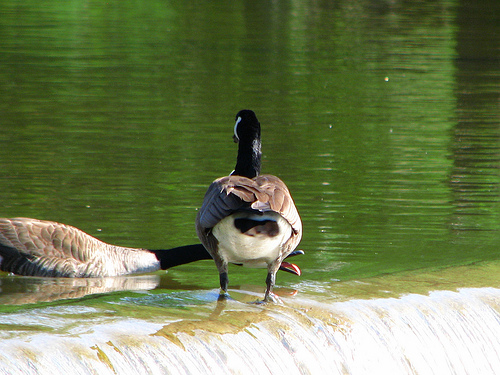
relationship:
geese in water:
[8, 125, 300, 309] [129, 27, 389, 79]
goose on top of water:
[197, 233, 300, 311] [129, 27, 389, 79]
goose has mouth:
[197, 233, 300, 311] [278, 242, 304, 273]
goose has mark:
[197, 233, 300, 311] [229, 114, 242, 140]